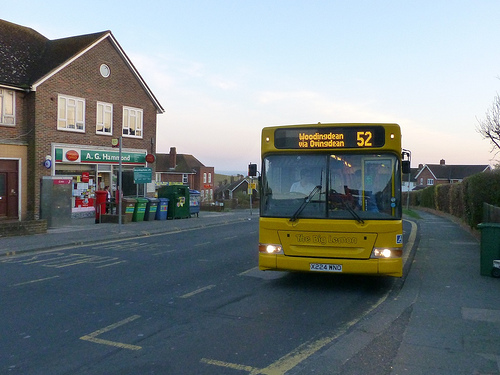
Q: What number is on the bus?
A: 52.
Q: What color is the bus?
A: Yellow.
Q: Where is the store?
A: Across the street.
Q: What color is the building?
A: Brown.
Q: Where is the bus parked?
A: Along the curb.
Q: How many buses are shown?
A: 1.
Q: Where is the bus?
A: Next to the curb.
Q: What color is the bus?
A: Yellow.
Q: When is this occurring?
A: At sunset.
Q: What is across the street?
A: A store.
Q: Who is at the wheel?
A: The bus driver.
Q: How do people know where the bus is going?
A: The sign on top.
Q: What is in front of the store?
A: Trash and recycling bins.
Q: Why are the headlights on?
A: It is getting dark.